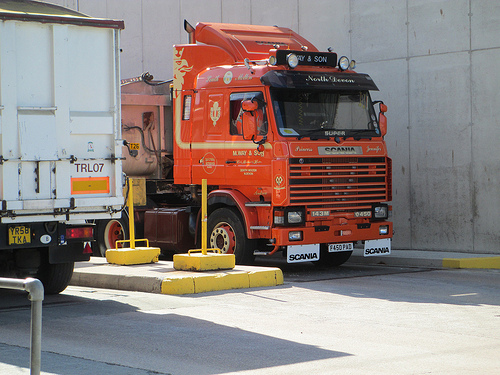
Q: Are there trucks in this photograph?
A: Yes, there is a truck.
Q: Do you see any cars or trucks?
A: Yes, there is a truck.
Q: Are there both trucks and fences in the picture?
A: No, there is a truck but no fences.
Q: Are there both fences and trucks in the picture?
A: No, there is a truck but no fences.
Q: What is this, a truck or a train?
A: This is a truck.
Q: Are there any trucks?
A: Yes, there is a truck.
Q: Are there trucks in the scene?
A: Yes, there is a truck.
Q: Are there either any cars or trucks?
A: Yes, there is a truck.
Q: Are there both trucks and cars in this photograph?
A: No, there is a truck but no cars.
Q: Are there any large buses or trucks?
A: Yes, there is a large truck.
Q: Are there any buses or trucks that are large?
A: Yes, the truck is large.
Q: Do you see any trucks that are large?
A: Yes, there is a large truck.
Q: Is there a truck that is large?
A: Yes, there is a truck that is large.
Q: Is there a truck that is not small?
A: Yes, there is a large truck.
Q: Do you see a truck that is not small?
A: Yes, there is a large truck.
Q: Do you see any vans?
A: No, there are no vans.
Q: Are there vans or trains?
A: No, there are no vans or trains.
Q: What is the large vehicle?
A: The vehicle is a truck.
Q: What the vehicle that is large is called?
A: The vehicle is a truck.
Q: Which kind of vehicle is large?
A: The vehicle is a truck.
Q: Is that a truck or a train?
A: That is a truck.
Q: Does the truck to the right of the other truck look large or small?
A: The truck is large.